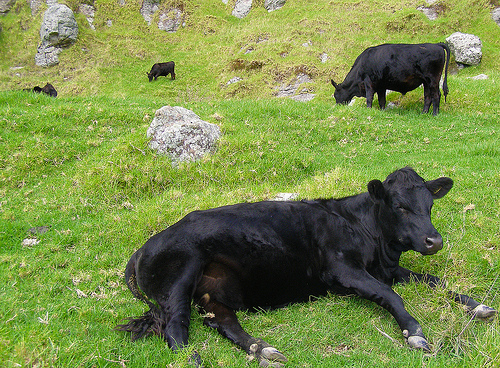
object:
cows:
[112, 165, 495, 367]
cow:
[144, 60, 175, 83]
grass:
[8, 100, 129, 175]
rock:
[144, 105, 226, 165]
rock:
[34, 3, 82, 69]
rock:
[439, 30, 482, 67]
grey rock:
[140, 1, 188, 31]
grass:
[78, 37, 161, 67]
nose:
[421, 235, 445, 250]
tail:
[439, 42, 453, 104]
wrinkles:
[340, 207, 397, 269]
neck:
[361, 191, 401, 256]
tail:
[111, 263, 170, 345]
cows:
[16, 83, 58, 99]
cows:
[328, 42, 451, 118]